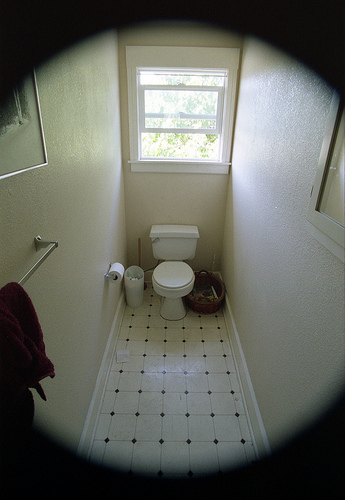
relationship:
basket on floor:
[184, 268, 226, 314] [177, 297, 225, 332]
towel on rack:
[0, 280, 58, 431] [17, 234, 60, 285]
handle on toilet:
[136, 235, 141, 264] [148, 223, 201, 321]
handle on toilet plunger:
[138, 235, 142, 267] [137, 236, 147, 292]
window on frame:
[136, 69, 227, 162] [130, 63, 230, 166]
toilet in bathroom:
[146, 221, 204, 323] [1, 0, 342, 496]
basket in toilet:
[184, 268, 226, 314] [146, 220, 199, 319]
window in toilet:
[136, 69, 227, 162] [148, 223, 201, 321]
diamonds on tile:
[145, 346, 199, 387] [93, 310, 259, 459]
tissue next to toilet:
[95, 252, 131, 285] [146, 226, 222, 323]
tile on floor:
[129, 336, 238, 470] [138, 323, 239, 455]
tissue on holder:
[104, 261, 125, 284] [103, 263, 120, 281]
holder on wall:
[104, 260, 126, 286] [73, 178, 129, 344]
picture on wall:
[0, 67, 48, 179] [53, 76, 106, 240]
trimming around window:
[127, 48, 241, 176] [127, 48, 232, 173]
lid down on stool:
[149, 257, 194, 291] [142, 218, 200, 321]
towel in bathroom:
[0, 280, 58, 431] [2, 26, 323, 495]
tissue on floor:
[112, 341, 135, 366] [130, 316, 218, 450]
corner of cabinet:
[298, 200, 326, 250] [278, 118, 344, 222]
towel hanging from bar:
[0, 280, 58, 431] [23, 229, 60, 292]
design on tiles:
[153, 363, 205, 449] [136, 361, 266, 431]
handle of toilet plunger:
[138, 235, 142, 267] [135, 235, 146, 293]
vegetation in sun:
[150, 76, 217, 156] [154, 103, 208, 153]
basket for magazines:
[177, 266, 231, 314] [199, 281, 223, 306]